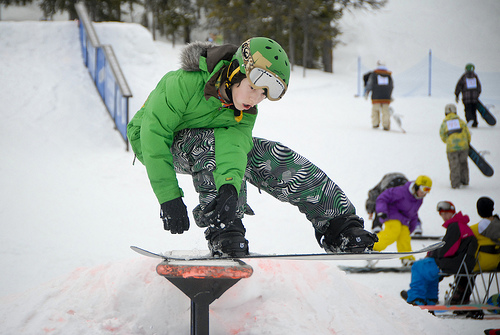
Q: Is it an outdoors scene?
A: Yes, it is outdoors.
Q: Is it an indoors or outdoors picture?
A: It is outdoors.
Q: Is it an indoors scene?
A: No, it is outdoors.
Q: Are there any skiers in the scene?
A: No, there are no skiers.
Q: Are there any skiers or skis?
A: No, there are no skiers or skis.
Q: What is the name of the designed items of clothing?
A: The clothing items are snow pants.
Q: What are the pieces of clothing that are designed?
A: The clothing items are snow pants.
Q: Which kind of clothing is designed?
A: The clothing is snow pants.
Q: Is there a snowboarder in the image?
A: Yes, there is a snowboarder.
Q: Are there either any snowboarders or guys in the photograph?
A: Yes, there is a snowboarder.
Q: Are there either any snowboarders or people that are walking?
A: Yes, the snowboarder is walking.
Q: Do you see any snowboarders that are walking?
A: Yes, there is a snowboarder that is walking.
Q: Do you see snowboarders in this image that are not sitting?
A: Yes, there is a snowboarder that is walking .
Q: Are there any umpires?
A: No, there are no umpires.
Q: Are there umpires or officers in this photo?
A: No, there are no umpires or officers.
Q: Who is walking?
A: The snowboarder is walking.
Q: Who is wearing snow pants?
A: The snowboarder is wearing snow pants.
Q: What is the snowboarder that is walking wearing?
A: The snowboarder is wearing snowpants.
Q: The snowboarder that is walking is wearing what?
A: The snowboarder is wearing snowpants.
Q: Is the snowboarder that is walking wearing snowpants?
A: Yes, the snowboarder is wearing snowpants.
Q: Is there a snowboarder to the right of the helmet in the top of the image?
A: Yes, there is a snowboarder to the right of the helmet.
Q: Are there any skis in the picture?
A: No, there are no skis.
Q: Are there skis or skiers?
A: No, there are no skis or skiers.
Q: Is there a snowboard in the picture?
A: Yes, there is a snowboard.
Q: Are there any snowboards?
A: Yes, there is a snowboard.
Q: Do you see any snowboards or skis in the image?
A: Yes, there is a snowboard.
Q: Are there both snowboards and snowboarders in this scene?
A: Yes, there are both a snowboard and a snowboarder.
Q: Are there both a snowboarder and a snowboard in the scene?
A: Yes, there are both a snowboard and a snowboarder.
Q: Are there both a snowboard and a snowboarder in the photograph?
A: Yes, there are both a snowboard and a snowboarder.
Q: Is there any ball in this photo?
A: No, there are no balls.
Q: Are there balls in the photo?
A: No, there are no balls.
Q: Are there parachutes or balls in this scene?
A: No, there are no balls or parachutes.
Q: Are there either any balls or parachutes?
A: No, there are no balls or parachutes.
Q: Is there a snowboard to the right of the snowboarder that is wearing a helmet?
A: Yes, there is a snowboard to the right of the snowboarder.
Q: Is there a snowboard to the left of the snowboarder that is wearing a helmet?
A: No, the snowboard is to the right of the snowboarder.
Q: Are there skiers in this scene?
A: No, there are no skiers.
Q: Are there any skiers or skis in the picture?
A: No, there are no skiers or skis.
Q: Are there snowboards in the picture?
A: Yes, there is a snowboard.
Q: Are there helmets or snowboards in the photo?
A: Yes, there is a snowboard.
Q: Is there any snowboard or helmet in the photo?
A: Yes, there is a snowboard.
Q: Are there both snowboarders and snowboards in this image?
A: Yes, there are both a snowboard and a snowboarder.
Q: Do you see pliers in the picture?
A: No, there are no pliers.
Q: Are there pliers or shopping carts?
A: No, there are no pliers or shopping carts.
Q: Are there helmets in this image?
A: Yes, there is a helmet.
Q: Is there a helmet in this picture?
A: Yes, there is a helmet.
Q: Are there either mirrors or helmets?
A: Yes, there is a helmet.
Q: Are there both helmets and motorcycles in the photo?
A: No, there is a helmet but no motorcycles.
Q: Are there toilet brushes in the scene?
A: No, there are no toilet brushes.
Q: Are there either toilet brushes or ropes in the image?
A: No, there are no toilet brushes or ropes.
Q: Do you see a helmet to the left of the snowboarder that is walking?
A: Yes, there is a helmet to the left of the snowboarder.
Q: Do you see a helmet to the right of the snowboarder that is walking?
A: No, the helmet is to the left of the snowboarder.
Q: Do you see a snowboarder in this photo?
A: Yes, there is a snowboarder.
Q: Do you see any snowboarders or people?
A: Yes, there is a snowboarder.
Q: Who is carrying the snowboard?
A: The snowboarder is carrying the snowboard.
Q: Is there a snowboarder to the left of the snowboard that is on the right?
A: Yes, there is a snowboarder to the left of the snowboard.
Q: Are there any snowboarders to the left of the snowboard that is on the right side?
A: Yes, there is a snowboarder to the left of the snowboard.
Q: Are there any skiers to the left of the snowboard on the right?
A: No, there is a snowboarder to the left of the snowboard.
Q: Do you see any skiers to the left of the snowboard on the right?
A: No, there is a snowboarder to the left of the snowboard.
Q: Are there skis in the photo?
A: No, there are no skis.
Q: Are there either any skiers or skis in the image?
A: No, there are no skis or skiers.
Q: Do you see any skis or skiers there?
A: No, there are no skis or skiers.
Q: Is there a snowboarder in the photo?
A: Yes, there is a snowboarder.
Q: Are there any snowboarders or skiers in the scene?
A: Yes, there is a snowboarder.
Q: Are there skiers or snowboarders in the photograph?
A: Yes, there is a snowboarder.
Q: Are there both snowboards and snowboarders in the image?
A: Yes, there are both a snowboarder and a snowboard.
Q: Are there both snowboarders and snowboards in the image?
A: Yes, there are both a snowboarder and a snowboard.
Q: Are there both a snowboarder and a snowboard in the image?
A: Yes, there are both a snowboarder and a snowboard.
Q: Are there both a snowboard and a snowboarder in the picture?
A: Yes, there are both a snowboarder and a snowboard.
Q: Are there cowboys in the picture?
A: No, there are no cowboys.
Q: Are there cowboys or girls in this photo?
A: No, there are no cowboys or girls.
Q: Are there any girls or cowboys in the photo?
A: No, there are no cowboys or girls.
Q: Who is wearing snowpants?
A: The snowboarder is wearing snowpants.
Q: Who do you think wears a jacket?
A: The snowboarder wears a jacket.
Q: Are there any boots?
A: Yes, there are boots.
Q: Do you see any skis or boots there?
A: Yes, there are boots.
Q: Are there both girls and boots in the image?
A: No, there are boots but no girls.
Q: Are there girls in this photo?
A: No, there are no girls.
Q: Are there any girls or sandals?
A: No, there are no girls or sandals.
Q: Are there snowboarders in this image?
A: Yes, there is a snowboarder.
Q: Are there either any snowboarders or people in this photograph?
A: Yes, there is a snowboarder.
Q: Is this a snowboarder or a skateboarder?
A: This is a snowboarder.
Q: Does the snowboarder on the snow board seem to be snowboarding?
A: Yes, the snowboarder is snowboarding.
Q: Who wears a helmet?
A: The snowboarder wears a helmet.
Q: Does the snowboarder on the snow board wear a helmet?
A: Yes, the snowboarder wears a helmet.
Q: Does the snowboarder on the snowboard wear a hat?
A: No, the snowboarder wears a helmet.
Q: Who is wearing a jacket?
A: The snowboarder is wearing a jacket.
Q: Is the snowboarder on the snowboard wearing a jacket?
A: Yes, the snowboarder is wearing a jacket.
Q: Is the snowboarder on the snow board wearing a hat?
A: No, the snowboarder is wearing a jacket.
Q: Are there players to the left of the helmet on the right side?
A: No, there is a snowboarder to the left of the helmet.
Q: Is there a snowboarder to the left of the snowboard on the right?
A: Yes, there is a snowboarder to the left of the snowboard.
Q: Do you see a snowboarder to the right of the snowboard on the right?
A: No, the snowboarder is to the left of the snowboard.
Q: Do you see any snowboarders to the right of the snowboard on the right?
A: No, the snowboarder is to the left of the snowboard.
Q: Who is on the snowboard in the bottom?
A: The snowboarder is on the snow board.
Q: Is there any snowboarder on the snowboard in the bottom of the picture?
A: Yes, there is a snowboarder on the snowboard.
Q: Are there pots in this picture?
A: No, there are no pots.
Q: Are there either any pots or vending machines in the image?
A: No, there are no pots or vending machines.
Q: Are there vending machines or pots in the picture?
A: No, there are no pots or vending machines.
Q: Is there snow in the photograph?
A: Yes, there is snow.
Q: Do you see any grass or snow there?
A: Yes, there is snow.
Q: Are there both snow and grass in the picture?
A: No, there is snow but no grass.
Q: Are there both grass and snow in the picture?
A: No, there is snow but no grass.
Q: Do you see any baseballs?
A: No, there are no baseballs.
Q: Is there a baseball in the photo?
A: No, there are no baseballs.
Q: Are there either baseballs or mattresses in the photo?
A: No, there are no baseballs or mattresses.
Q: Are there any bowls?
A: No, there are no bowls.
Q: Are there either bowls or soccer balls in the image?
A: No, there are no bowls or soccer balls.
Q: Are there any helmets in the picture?
A: Yes, there is a helmet.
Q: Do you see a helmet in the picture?
A: Yes, there is a helmet.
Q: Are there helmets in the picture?
A: Yes, there is a helmet.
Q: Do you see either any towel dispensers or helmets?
A: Yes, there is a helmet.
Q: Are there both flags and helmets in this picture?
A: No, there is a helmet but no flags.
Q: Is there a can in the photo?
A: No, there are no cans.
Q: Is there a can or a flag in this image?
A: No, there are no cans or flags.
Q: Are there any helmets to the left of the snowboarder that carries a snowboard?
A: Yes, there is a helmet to the left of the snowboarder.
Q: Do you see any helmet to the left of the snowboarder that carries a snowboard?
A: Yes, there is a helmet to the left of the snowboarder.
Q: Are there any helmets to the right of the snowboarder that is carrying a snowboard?
A: No, the helmet is to the left of the snowboarder.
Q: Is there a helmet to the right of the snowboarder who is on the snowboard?
A: Yes, there is a helmet to the right of the snowboarder.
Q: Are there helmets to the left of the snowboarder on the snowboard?
A: No, the helmet is to the right of the snowboarder.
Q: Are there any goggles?
A: Yes, there are goggles.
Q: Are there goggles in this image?
A: Yes, there are goggles.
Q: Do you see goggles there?
A: Yes, there are goggles.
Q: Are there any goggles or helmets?
A: Yes, there are goggles.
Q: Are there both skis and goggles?
A: No, there are goggles but no skis.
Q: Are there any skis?
A: No, there are no skis.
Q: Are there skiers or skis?
A: No, there are no skis or skiers.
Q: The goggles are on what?
A: The goggles are on the helmet.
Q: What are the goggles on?
A: The goggles are on the helmet.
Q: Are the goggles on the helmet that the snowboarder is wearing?
A: Yes, the goggles are on the helmet.